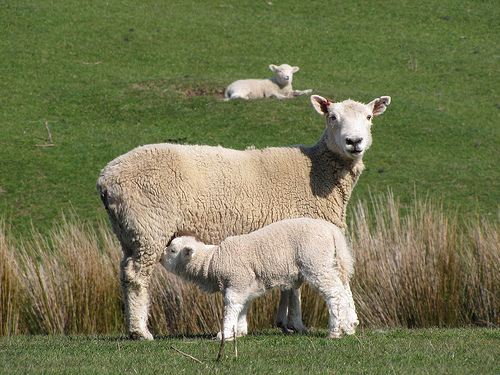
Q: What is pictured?
A: A mama sheep nursing her baby.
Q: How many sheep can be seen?
A: Three.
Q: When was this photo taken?
A: During the day.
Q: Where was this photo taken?
A: In a field.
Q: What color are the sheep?
A: Beige and white.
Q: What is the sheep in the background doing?
A: Laying down.